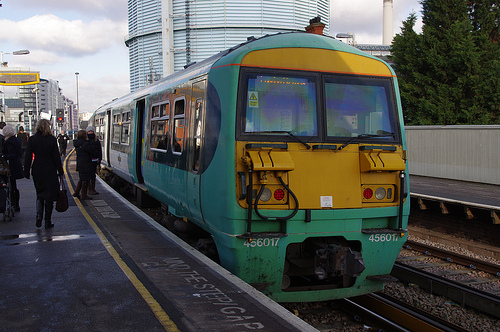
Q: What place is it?
A: It is a sidewalk.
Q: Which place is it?
A: It is a sidewalk.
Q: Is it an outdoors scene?
A: Yes, it is outdoors.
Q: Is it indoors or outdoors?
A: It is outdoors.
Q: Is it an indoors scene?
A: No, it is outdoors.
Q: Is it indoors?
A: No, it is outdoors.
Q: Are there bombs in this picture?
A: No, there are no bombs.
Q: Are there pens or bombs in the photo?
A: No, there are no bombs or pens.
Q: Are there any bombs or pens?
A: No, there are no bombs or pens.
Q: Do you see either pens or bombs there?
A: No, there are no bombs or pens.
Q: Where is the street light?
A: The street light is on the street.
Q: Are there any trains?
A: Yes, there is a train.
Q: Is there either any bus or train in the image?
A: Yes, there is a train.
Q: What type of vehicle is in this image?
A: The vehicle is a train.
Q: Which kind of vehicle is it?
A: The vehicle is a train.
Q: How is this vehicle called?
A: This is a train.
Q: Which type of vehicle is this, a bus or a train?
A: This is a train.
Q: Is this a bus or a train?
A: This is a train.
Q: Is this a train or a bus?
A: This is a train.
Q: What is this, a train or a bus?
A: This is a train.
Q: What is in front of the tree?
A: The train is in front of the tree.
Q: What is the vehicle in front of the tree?
A: The vehicle is a train.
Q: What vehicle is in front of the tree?
A: The vehicle is a train.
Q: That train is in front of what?
A: The train is in front of the tree.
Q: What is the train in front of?
A: The train is in front of the tree.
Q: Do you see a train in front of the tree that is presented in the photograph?
A: Yes, there is a train in front of the tree.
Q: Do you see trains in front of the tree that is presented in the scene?
A: Yes, there is a train in front of the tree.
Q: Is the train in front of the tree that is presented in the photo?
A: Yes, the train is in front of the tree.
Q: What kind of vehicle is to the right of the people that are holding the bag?
A: The vehicle is a train.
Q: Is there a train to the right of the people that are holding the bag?
A: Yes, there is a train to the right of the people.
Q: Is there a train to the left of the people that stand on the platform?
A: No, the train is to the right of the people.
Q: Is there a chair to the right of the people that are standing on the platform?
A: No, there is a train to the right of the people.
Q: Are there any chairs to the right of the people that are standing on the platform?
A: No, there is a train to the right of the people.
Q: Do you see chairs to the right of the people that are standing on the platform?
A: No, there is a train to the right of the people.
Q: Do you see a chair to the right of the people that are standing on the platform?
A: No, there is a train to the right of the people.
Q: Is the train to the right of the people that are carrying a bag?
A: Yes, the train is to the right of the people.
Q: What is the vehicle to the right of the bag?
A: The vehicle is a train.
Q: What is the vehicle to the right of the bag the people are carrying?
A: The vehicle is a train.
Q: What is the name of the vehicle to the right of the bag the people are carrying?
A: The vehicle is a train.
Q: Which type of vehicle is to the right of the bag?
A: The vehicle is a train.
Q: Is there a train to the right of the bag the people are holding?
A: Yes, there is a train to the right of the bag.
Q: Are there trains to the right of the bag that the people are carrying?
A: Yes, there is a train to the right of the bag.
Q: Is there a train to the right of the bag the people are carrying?
A: Yes, there is a train to the right of the bag.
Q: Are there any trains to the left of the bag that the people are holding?
A: No, the train is to the right of the bag.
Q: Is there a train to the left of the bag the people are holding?
A: No, the train is to the right of the bag.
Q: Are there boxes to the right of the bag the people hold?
A: No, there is a train to the right of the bag.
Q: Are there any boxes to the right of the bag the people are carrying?
A: No, there is a train to the right of the bag.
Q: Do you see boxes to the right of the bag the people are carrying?
A: No, there is a train to the right of the bag.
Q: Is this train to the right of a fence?
A: No, the train is to the right of the bag.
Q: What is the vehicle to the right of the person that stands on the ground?
A: The vehicle is a train.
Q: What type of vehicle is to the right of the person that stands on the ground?
A: The vehicle is a train.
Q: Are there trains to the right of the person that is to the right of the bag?
A: Yes, there is a train to the right of the person.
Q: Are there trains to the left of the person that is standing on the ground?
A: No, the train is to the right of the person.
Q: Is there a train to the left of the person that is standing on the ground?
A: No, the train is to the right of the person.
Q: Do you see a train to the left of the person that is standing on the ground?
A: No, the train is to the right of the person.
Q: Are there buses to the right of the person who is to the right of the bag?
A: No, there is a train to the right of the person.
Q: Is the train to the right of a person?
A: Yes, the train is to the right of a person.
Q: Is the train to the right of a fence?
A: No, the train is to the right of a person.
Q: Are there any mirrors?
A: No, there are no mirrors.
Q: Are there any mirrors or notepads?
A: No, there are no mirrors or notepads.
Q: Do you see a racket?
A: No, there are no rackets.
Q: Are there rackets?
A: No, there are no rackets.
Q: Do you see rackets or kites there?
A: No, there are no rackets or kites.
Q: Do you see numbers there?
A: Yes, there are numbers.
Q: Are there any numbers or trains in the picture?
A: Yes, there are numbers.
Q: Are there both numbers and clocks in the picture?
A: No, there are numbers but no clocks.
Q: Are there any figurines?
A: No, there are no figurines.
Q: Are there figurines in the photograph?
A: No, there are no figurines.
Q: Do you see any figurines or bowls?
A: No, there are no figurines or bowls.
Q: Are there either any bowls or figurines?
A: No, there are no figurines or bowls.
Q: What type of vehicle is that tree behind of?
A: The tree is behind the train.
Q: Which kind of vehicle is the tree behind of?
A: The tree is behind the train.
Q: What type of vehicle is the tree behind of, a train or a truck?
A: The tree is behind a train.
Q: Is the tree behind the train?
A: Yes, the tree is behind the train.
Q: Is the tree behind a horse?
A: No, the tree is behind the train.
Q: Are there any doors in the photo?
A: Yes, there is a door.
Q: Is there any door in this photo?
A: Yes, there is a door.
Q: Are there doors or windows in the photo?
A: Yes, there is a door.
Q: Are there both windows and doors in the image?
A: Yes, there are both a door and a window.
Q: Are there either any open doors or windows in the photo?
A: Yes, there is an open door.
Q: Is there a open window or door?
A: Yes, there is an open door.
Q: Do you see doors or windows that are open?
A: Yes, the door is open.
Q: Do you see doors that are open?
A: Yes, there is an open door.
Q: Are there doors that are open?
A: Yes, there is a door that is open.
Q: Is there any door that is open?
A: Yes, there is a door that is open.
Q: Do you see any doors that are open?
A: Yes, there is a door that is open.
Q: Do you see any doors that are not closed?
A: Yes, there is a open door.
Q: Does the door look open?
A: Yes, the door is open.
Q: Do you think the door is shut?
A: No, the door is open.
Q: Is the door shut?
A: No, the door is open.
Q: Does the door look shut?
A: No, the door is open.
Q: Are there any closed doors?
A: No, there is a door but it is open.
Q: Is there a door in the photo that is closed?
A: No, there is a door but it is open.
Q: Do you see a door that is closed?
A: No, there is a door but it is open.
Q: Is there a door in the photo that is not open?
A: No, there is a door but it is open.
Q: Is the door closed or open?
A: The door is open.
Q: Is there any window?
A: Yes, there are windows.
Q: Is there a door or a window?
A: Yes, there are windows.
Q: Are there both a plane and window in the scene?
A: No, there are windows but no airplanes.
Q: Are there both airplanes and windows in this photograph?
A: No, there are windows but no airplanes.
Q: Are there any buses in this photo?
A: No, there are no buses.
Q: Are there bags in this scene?
A: Yes, there is a bag.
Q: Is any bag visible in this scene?
A: Yes, there is a bag.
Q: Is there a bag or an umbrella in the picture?
A: Yes, there is a bag.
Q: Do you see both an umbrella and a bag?
A: No, there is a bag but no umbrellas.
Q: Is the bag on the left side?
A: Yes, the bag is on the left of the image.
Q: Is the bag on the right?
A: No, the bag is on the left of the image.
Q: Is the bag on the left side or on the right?
A: The bag is on the left of the image.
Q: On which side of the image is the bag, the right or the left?
A: The bag is on the left of the image.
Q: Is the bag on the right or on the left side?
A: The bag is on the left of the image.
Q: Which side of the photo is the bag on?
A: The bag is on the left of the image.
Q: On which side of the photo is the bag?
A: The bag is on the left of the image.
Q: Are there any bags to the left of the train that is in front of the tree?
A: Yes, there is a bag to the left of the train.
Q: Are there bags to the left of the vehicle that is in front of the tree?
A: Yes, there is a bag to the left of the train.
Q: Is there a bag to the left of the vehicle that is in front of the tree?
A: Yes, there is a bag to the left of the train.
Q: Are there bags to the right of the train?
A: No, the bag is to the left of the train.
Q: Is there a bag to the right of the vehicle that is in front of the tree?
A: No, the bag is to the left of the train.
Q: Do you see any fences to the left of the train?
A: No, there is a bag to the left of the train.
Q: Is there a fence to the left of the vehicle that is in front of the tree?
A: No, there is a bag to the left of the train.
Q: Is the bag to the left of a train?
A: Yes, the bag is to the left of a train.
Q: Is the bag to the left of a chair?
A: No, the bag is to the left of a train.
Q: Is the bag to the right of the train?
A: No, the bag is to the left of the train.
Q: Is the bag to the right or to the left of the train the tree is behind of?
A: The bag is to the left of the train.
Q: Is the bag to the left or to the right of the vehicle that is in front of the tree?
A: The bag is to the left of the train.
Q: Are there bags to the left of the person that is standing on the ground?
A: Yes, there is a bag to the left of the person.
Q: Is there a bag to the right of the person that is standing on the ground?
A: No, the bag is to the left of the person.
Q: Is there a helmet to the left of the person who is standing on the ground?
A: No, there is a bag to the left of the person.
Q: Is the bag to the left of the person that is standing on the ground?
A: Yes, the bag is to the left of the person.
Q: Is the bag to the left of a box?
A: No, the bag is to the left of the person.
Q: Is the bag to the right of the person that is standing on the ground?
A: No, the bag is to the left of the person.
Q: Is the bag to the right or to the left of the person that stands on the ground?
A: The bag is to the left of the person.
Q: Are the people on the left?
A: Yes, the people are on the left of the image.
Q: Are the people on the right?
A: No, the people are on the left of the image.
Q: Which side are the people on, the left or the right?
A: The people are on the left of the image.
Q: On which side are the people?
A: The people are on the left of the image.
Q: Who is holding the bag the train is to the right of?
A: The people are holding the bag.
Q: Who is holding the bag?
A: The people are holding the bag.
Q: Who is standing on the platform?
A: The people are standing on the platform.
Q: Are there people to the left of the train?
A: Yes, there are people to the left of the train.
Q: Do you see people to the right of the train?
A: No, the people are to the left of the train.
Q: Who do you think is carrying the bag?
A: The people are carrying the bag.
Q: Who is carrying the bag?
A: The people are carrying the bag.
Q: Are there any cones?
A: No, there are no cones.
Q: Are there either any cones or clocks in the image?
A: No, there are no cones or clocks.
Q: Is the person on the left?
A: Yes, the person is on the left of the image.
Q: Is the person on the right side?
A: No, the person is on the left of the image.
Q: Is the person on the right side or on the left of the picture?
A: The person is on the left of the image.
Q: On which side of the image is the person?
A: The person is on the left of the image.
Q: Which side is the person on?
A: The person is on the left of the image.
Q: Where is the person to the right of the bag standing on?
A: The person is standing on the ground.